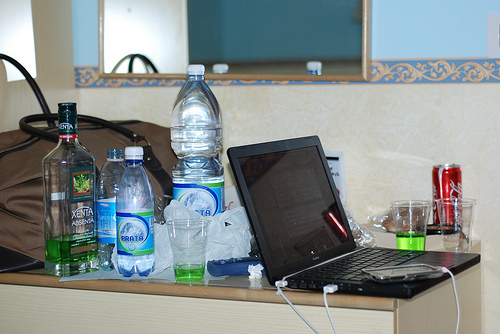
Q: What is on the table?
A: Laptop.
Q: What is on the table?
A: Computer.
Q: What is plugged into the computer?
A: A phone.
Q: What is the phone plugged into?
A: A laptop.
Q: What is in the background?
A: A mirror.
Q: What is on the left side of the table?
A: A bag.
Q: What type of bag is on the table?
A: A duffle bag.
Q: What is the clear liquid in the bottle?
A: Water.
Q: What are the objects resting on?
A: A table.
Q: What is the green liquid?
A: Liquor.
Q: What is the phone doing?
A: Charging.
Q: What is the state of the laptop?
A: Turned off.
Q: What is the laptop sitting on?
A: A counter.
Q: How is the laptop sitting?
A: Open.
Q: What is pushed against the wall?
A: A soda can.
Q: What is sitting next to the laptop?
A: A soda can.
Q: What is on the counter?
A: A laptop.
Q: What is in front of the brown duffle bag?
A: A glass bottle.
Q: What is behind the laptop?
A: A water bottle.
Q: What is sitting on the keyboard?
A: A cell phone.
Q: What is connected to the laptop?
A: Cables.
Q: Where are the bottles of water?
A: On the counter.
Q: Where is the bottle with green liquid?
A: On the counter.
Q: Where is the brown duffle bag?
A: On the counter.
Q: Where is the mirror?
A: On the wall.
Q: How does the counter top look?
A: Cluttered.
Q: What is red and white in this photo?
A: The coke can.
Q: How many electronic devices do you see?
A: 2.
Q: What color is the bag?
A: Brown.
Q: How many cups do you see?
A: 3.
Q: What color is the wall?
A: Brown and blue.